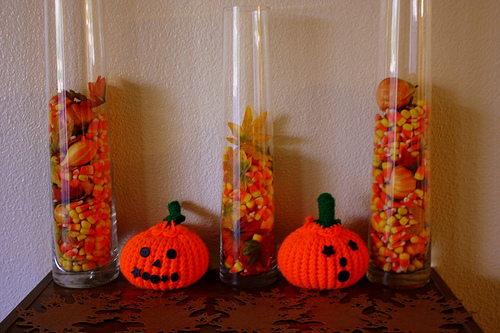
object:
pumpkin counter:
[118, 191, 370, 291]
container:
[45, 1, 121, 289]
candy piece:
[376, 77, 419, 111]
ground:
[440, 136, 473, 183]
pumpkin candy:
[382, 165, 417, 200]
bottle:
[364, 0, 432, 290]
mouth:
[131, 266, 179, 283]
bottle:
[219, 4, 278, 288]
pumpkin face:
[131, 247, 179, 284]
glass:
[45, 0, 122, 289]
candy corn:
[413, 173, 424, 181]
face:
[321, 239, 359, 282]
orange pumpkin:
[277, 193, 370, 290]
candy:
[221, 112, 277, 284]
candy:
[368, 72, 436, 274]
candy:
[48, 82, 116, 273]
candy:
[385, 213, 400, 225]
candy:
[389, 241, 419, 266]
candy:
[380, 156, 391, 183]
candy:
[246, 181, 260, 197]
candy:
[255, 205, 267, 224]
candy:
[227, 259, 244, 274]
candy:
[90, 163, 107, 179]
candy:
[87, 116, 104, 136]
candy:
[76, 203, 92, 223]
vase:
[45, 0, 117, 288]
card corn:
[222, 146, 274, 222]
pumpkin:
[120, 200, 210, 292]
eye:
[141, 247, 150, 257]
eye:
[166, 249, 177, 260]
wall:
[0, 0, 499, 333]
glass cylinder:
[219, 5, 276, 286]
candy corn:
[244, 193, 253, 202]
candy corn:
[251, 190, 261, 198]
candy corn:
[263, 167, 271, 174]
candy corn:
[255, 214, 261, 221]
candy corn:
[226, 183, 232, 190]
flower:
[225, 105, 271, 147]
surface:
[14, 288, 476, 333]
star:
[131, 266, 141, 278]